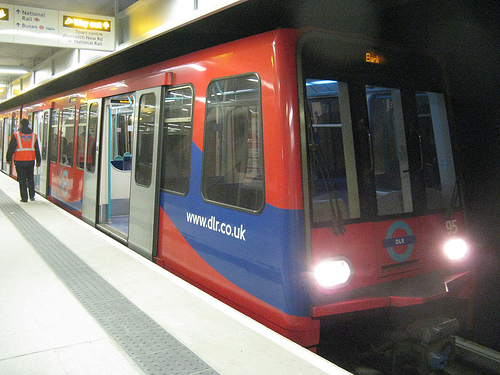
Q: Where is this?
A: This is at the station.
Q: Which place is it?
A: It is a station.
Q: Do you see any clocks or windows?
A: Yes, there is a window.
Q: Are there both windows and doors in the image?
A: Yes, there are both a window and a door.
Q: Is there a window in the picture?
A: Yes, there is a window.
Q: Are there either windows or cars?
A: Yes, there is a window.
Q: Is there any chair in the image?
A: No, there are no chairs.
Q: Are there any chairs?
A: No, there are no chairs.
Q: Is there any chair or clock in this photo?
A: No, there are no chairs or clocks.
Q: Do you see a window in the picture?
A: Yes, there is a window.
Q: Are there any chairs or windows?
A: Yes, there is a window.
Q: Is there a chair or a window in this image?
A: Yes, there is a window.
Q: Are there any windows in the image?
A: Yes, there is a window.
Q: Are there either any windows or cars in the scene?
A: Yes, there is a window.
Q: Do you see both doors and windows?
A: Yes, there are both a window and a door.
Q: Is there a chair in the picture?
A: No, there are no chairs.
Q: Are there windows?
A: Yes, there is a window.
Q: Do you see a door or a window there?
A: Yes, there is a window.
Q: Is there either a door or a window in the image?
A: Yes, there is a window.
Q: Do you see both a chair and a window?
A: No, there is a window but no chairs.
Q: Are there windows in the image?
A: Yes, there is a window.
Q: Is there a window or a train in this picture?
A: Yes, there is a window.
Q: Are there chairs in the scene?
A: No, there are no chairs.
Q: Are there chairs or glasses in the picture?
A: No, there are no chairs or glasses.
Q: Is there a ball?
A: No, there are no balls.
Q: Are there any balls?
A: No, there are no balls.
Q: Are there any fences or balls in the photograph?
A: No, there are no balls or fences.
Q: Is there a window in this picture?
A: Yes, there is a window.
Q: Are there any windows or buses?
A: Yes, there is a window.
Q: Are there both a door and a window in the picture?
A: Yes, there are both a window and a door.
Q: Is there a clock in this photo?
A: No, there are no clocks.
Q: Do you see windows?
A: Yes, there is a window.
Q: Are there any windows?
A: Yes, there is a window.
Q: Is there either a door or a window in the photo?
A: Yes, there is a window.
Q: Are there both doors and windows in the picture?
A: Yes, there are both a window and a door.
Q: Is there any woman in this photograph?
A: No, there are no women.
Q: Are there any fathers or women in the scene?
A: No, there are no women or fathers.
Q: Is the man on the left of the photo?
A: Yes, the man is on the left of the image.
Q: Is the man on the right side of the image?
A: No, the man is on the left of the image.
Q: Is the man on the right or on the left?
A: The man is on the left of the image.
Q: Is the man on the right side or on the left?
A: The man is on the left of the image.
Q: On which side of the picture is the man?
A: The man is on the left of the image.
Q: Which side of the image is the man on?
A: The man is on the left of the image.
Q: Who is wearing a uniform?
A: The man is wearing a uniform.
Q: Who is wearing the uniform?
A: The man is wearing a uniform.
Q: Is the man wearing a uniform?
A: Yes, the man is wearing a uniform.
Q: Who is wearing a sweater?
A: The man is wearing a sweater.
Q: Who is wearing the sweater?
A: The man is wearing a sweater.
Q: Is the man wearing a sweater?
A: Yes, the man is wearing a sweater.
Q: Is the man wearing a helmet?
A: No, the man is wearing a sweater.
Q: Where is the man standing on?
A: The man is standing on the station.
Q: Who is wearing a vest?
A: The man is wearing a vest.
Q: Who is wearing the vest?
A: The man is wearing a vest.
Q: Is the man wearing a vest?
A: Yes, the man is wearing a vest.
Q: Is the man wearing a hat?
A: No, the man is wearing a vest.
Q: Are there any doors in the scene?
A: Yes, there is a door.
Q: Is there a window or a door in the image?
A: Yes, there is a door.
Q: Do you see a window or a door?
A: Yes, there is a door.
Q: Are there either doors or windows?
A: Yes, there is a door.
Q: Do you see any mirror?
A: No, there are no mirrors.